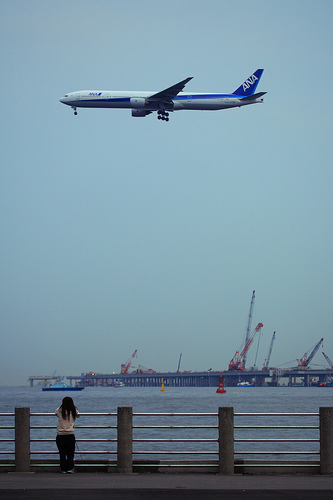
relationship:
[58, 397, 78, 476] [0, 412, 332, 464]
girl on bars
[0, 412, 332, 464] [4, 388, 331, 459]
bars near water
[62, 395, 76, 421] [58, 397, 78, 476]
hair on girl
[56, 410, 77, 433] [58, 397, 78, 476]
shirt on girl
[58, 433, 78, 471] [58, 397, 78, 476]
pants on girl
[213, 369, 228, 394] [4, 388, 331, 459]
buoy on water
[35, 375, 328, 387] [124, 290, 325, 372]
deck with cranes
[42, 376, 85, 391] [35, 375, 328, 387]
blue passing deck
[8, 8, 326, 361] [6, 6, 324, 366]
blue overhead sky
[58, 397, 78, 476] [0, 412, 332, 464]
woman taller than bars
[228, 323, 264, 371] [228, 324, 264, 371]
crane huge crane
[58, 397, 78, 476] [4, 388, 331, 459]
woman looking at ocean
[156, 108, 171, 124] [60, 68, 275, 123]
wheels on plane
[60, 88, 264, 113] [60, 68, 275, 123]
white flying plane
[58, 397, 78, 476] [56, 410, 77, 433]
girl in shirt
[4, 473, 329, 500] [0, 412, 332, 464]
boardwalk with bars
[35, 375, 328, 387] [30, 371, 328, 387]
bridge in deck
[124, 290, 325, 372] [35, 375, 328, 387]
equipment building bridge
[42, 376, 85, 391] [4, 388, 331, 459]
blue on water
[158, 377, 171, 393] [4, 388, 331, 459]
buoy on water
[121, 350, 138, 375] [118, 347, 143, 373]
crane tall crane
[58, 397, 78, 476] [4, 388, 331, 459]
woman looking at water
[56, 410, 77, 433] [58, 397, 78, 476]
shirt worn by women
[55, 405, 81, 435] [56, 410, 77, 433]
shirt sleeve shirt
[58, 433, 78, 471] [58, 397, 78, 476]
sweatpants worn by woman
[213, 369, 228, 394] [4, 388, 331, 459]
dinghy in water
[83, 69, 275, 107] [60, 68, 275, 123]
blue flying plane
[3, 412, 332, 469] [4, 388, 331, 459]
bars next to water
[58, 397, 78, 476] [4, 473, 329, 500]
woman on sidewalk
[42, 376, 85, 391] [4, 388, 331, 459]
blue in water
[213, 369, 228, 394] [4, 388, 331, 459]
buoy in water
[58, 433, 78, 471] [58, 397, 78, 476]
pants on woman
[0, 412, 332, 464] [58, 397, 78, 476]
bars protecting bystanders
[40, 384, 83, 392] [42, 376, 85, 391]
blue smaller blue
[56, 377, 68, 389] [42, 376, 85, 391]
white smaller blue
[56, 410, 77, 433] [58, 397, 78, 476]
sweatshirt on woman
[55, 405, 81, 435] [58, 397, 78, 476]
shirt on woman